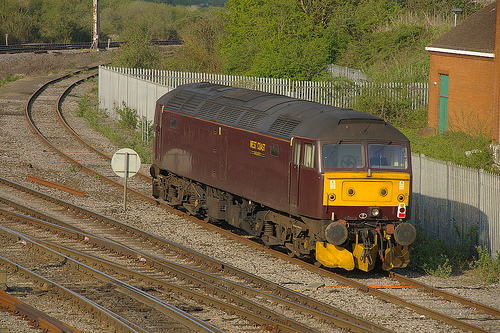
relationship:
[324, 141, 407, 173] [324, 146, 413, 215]
windows in front of train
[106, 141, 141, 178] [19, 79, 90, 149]
sign between traintrack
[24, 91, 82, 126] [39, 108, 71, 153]
railroadtracks lined with gravel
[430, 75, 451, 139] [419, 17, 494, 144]
door on building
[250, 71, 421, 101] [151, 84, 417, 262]
fence behind train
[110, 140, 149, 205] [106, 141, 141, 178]
back of sign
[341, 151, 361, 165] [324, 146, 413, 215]
steeringwheel of train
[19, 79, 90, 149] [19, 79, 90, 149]
traintrack has traintrack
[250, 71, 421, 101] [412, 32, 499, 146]
fence surrounding structure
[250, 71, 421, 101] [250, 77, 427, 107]
fence made of fence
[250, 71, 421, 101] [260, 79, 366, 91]
fence painted white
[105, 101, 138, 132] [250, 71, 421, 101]
weeds outside fence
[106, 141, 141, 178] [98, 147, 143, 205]
round sign on post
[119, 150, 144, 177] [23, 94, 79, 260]
round sign between traintracks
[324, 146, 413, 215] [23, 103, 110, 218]
train sitting on traintracks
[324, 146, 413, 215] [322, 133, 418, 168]
train has no driver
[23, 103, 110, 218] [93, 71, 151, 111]
traintracks closest to fence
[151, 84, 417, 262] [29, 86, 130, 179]
traincar on track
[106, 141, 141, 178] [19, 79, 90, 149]
sign on traintrack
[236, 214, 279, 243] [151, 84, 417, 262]
wheels under car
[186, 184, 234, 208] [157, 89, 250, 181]
gears under traincar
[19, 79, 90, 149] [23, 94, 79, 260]
curve in train tracks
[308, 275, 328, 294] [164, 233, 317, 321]
wood on ground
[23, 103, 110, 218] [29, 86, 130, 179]
sets of track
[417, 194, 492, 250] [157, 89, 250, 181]
shadow of traincar